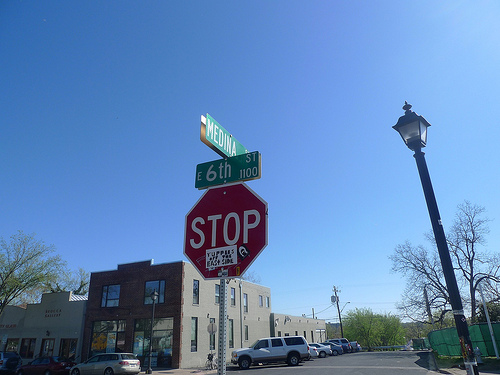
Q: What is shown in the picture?
A: A small town.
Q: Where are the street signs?
A: On a pole.